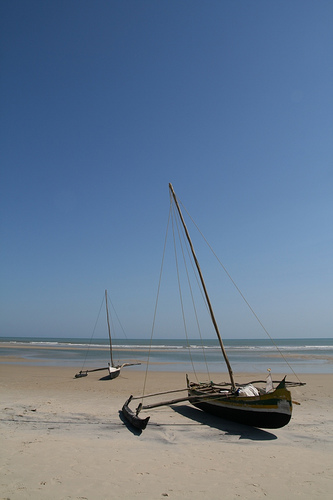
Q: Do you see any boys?
A: No, there are no boys.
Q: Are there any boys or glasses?
A: No, there are no boys or glasses.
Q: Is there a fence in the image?
A: No, there are no fences.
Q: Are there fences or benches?
A: No, there are no fences or benches.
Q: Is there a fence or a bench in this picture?
A: No, there are no fences or benches.